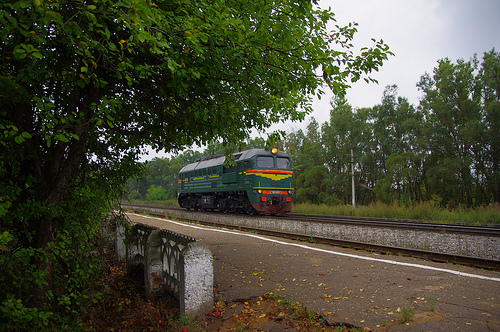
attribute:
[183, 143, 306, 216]
train — green , moving, yellow, below, here, red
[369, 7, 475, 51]
sky — close, dark, white, here, cloudy, above, grey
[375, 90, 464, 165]
tree — dark, here, green, close, large , lush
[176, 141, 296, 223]
train — single 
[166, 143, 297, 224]
train — green 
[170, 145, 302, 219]
train — green 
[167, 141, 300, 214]
train — green , single 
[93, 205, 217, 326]
fence — cement , white , old 